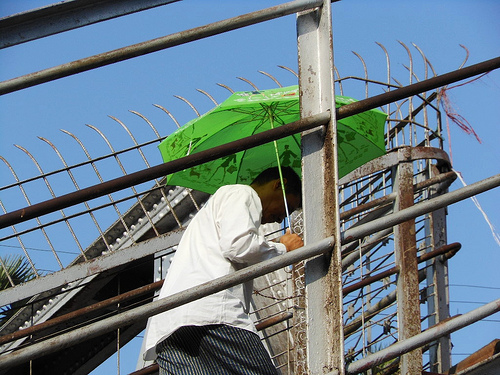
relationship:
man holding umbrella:
[146, 169, 303, 371] [151, 84, 389, 197]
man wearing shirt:
[140, 164, 301, 375] [138, 184, 299, 356]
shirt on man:
[163, 175, 282, 335] [126, 91, 344, 372]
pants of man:
[138, 327, 261, 373] [155, 165, 346, 363]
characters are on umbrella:
[275, 138, 299, 172] [149, 80, 396, 201]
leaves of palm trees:
[0, 255, 37, 291] [1, 255, 51, 320]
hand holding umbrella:
[282, 226, 300, 249] [159, 87, 381, 194]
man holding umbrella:
[140, 164, 301, 375] [124, 65, 414, 203]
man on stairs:
[140, 164, 301, 375] [366, 340, 499, 374]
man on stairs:
[140, 164, 301, 375] [0, 185, 201, 373]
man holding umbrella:
[140, 164, 301, 375] [153, 74, 393, 196]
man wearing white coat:
[140, 164, 301, 375] [142, 184, 287, 361]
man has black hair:
[140, 164, 301, 375] [251, 166, 302, 206]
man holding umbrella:
[140, 164, 301, 375] [161, 83, 391, 231]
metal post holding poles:
[392, 147, 422, 371] [339, 146, 449, 372]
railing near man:
[2, 1, 498, 372] [154, 158, 311, 373]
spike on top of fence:
[397, 33, 409, 56] [1, 35, 472, 374]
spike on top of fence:
[274, 60, 297, 77] [1, 35, 472, 374]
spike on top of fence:
[212, 81, 232, 93] [1, 35, 472, 374]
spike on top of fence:
[151, 97, 175, 116] [1, 35, 472, 374]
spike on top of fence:
[33, 133, 60, 150] [1, 35, 472, 374]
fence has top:
[1, 35, 472, 374] [1, 39, 473, 194]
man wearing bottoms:
[140, 164, 301, 375] [136, 323, 251, 373]